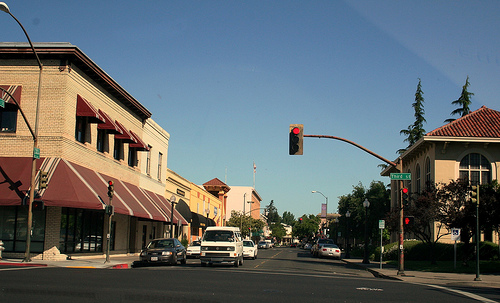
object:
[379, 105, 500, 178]
roof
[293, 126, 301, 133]
light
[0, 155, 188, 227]
brown awning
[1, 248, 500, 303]
streets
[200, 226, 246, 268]
cars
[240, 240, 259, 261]
car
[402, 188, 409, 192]
red light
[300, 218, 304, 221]
red light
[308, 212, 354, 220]
bridge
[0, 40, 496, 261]
building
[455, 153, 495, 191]
window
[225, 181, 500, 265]
trees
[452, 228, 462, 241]
sign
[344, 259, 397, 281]
curb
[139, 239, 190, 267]
car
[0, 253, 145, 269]
curb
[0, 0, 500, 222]
sky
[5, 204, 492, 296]
foreground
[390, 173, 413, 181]
green sign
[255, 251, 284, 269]
lines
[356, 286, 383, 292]
hole cover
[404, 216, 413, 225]
signal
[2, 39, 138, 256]
building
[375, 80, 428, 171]
tree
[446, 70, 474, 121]
tree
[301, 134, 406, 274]
pole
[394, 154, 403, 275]
pole